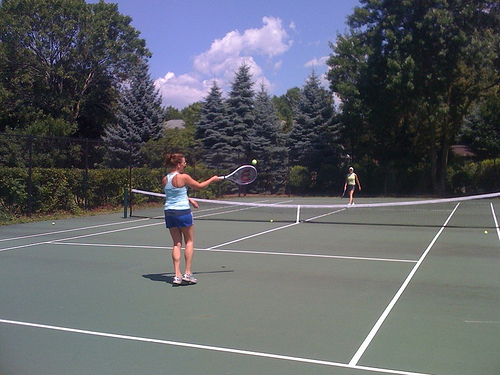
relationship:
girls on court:
[116, 157, 446, 295] [16, 209, 496, 373]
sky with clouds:
[125, 1, 372, 112] [146, 14, 282, 107]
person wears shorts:
[159, 153, 221, 287] [160, 208, 196, 229]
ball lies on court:
[482, 228, 490, 236] [0, 195, 500, 374]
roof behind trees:
[174, 120, 187, 128] [3, 0, 498, 194]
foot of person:
[183, 271, 198, 283] [159, 153, 221, 287]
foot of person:
[167, 266, 193, 290] [162, 151, 222, 288]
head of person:
[164, 148, 188, 172] [150, 171, 248, 274]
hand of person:
[209, 173, 222, 185] [162, 151, 222, 288]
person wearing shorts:
[342, 167, 362, 206] [346, 185, 357, 190]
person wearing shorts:
[159, 153, 221, 287] [162, 205, 194, 230]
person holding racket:
[159, 153, 221, 287] [218, 162, 259, 187]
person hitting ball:
[153, 143, 221, 293] [251, 159, 257, 165]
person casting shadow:
[159, 153, 221, 287] [140, 263, 239, 290]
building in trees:
[449, 139, 486, 162] [351, 43, 486, 166]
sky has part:
[125, 1, 372, 112] [304, 50, 328, 71]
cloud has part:
[154, 13, 339, 116] [219, 43, 235, 58]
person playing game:
[159, 153, 221, 287] [3, 148, 493, 373]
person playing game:
[333, 164, 361, 208] [3, 148, 493, 373]